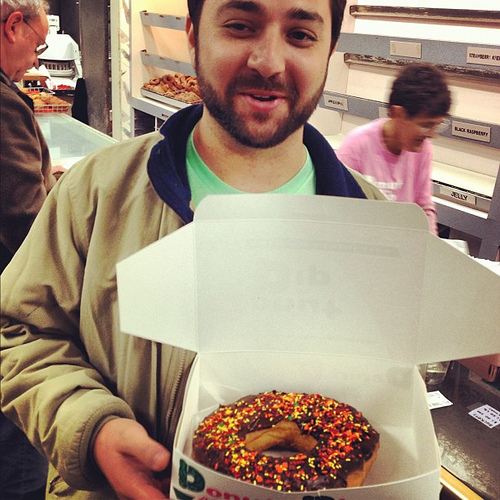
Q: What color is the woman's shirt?
A: Pink.